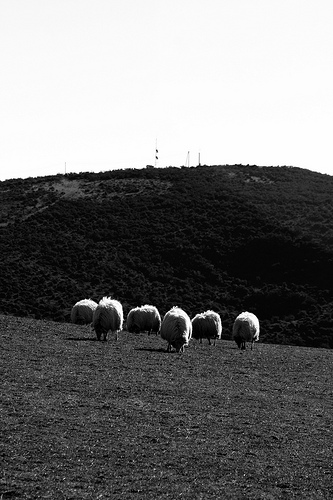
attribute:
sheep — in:
[74, 292, 97, 326]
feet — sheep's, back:
[106, 331, 121, 340]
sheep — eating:
[90, 295, 124, 340]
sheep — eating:
[230, 310, 260, 350]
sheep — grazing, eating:
[190, 308, 222, 345]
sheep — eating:
[124, 303, 161, 336]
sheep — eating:
[69, 297, 99, 324]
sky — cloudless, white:
[0, 0, 331, 181]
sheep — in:
[71, 293, 94, 320]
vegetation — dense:
[40, 105, 332, 309]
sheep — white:
[58, 283, 266, 361]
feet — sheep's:
[103, 338, 108, 342]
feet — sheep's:
[96, 335, 101, 337]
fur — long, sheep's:
[72, 294, 257, 330]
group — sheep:
[64, 292, 266, 349]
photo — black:
[7, 1, 322, 492]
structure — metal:
[153, 136, 159, 172]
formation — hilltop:
[10, 163, 316, 333]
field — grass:
[7, 306, 323, 490]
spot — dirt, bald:
[32, 178, 87, 200]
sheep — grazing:
[232, 309, 261, 355]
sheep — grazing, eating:
[160, 305, 191, 352]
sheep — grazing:
[123, 302, 161, 334]